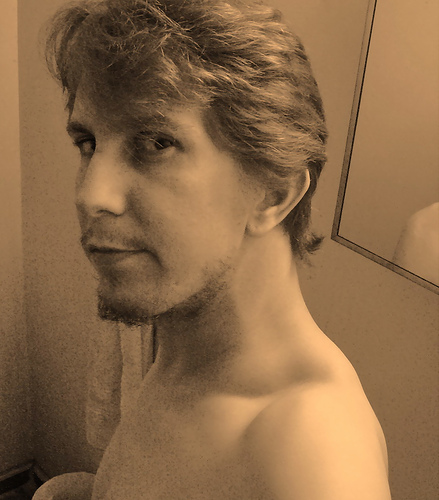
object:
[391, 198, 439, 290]
reflection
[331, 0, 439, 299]
mirror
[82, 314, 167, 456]
curtain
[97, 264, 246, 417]
shadow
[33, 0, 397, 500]
man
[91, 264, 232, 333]
beard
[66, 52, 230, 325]
face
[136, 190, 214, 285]
jaw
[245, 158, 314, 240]
ear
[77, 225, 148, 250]
lips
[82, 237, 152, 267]
mouth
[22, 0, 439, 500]
on wall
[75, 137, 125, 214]
nose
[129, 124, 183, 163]
eye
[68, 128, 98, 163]
eye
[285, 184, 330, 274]
tail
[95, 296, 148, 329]
mustach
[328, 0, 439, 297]
metal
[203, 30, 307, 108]
light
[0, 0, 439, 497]
bathroom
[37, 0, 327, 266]
blonde hair